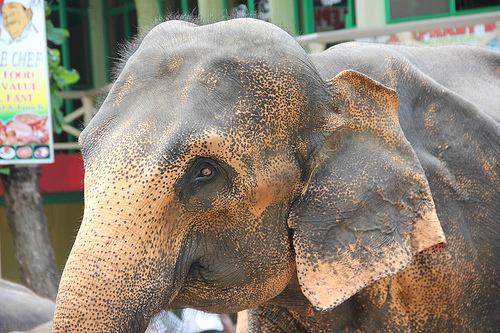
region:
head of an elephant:
[55, 11, 358, 316]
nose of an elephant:
[49, 238, 169, 329]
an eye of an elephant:
[179, 120, 264, 191]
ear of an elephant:
[217, 67, 454, 312]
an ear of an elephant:
[239, 37, 427, 304]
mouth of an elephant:
[148, 254, 228, 319]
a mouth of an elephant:
[137, 243, 241, 305]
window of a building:
[60, 7, 96, 84]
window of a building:
[102, 21, 119, 73]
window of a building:
[388, 0, 457, 25]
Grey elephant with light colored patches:
[45, 14, 498, 331]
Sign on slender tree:
[3, 4, 68, 301]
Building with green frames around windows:
[34, 2, 499, 144]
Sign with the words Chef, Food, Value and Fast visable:
[0, 0, 60, 169]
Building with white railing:
[5, 6, 498, 306]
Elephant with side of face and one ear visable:
[51, 13, 497, 331]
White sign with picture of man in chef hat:
[1, 0, 53, 170]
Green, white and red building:
[3, 4, 498, 281]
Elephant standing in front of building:
[5, 8, 498, 331]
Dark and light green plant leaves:
[38, 2, 81, 139]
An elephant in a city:
[47, 11, 482, 331]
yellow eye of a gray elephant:
[182, 154, 219, 184]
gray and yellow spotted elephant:
[50, 16, 497, 330]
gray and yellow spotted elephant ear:
[288, 69, 445, 309]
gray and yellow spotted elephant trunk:
[53, 135, 198, 330]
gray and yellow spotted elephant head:
[50, 17, 326, 330]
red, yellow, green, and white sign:
[0, 0, 53, 165]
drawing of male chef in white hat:
[1, 0, 39, 42]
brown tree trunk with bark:
[4, 163, 58, 298]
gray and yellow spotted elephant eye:
[172, 153, 237, 202]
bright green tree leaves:
[42, 1, 79, 134]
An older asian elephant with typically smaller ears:
[286, 70, 446, 315]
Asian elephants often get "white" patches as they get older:
[50, 125, 265, 330]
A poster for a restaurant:
[0, 0, 55, 165]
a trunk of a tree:
[0, 155, 55, 300]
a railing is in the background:
[55, 86, 115, 141]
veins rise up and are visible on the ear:
[345, 181, 405, 236]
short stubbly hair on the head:
[110, 12, 196, 77]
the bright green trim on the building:
[51, 0, 496, 75]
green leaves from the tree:
[41, 16, 76, 131]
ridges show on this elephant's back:
[382, 42, 499, 201]